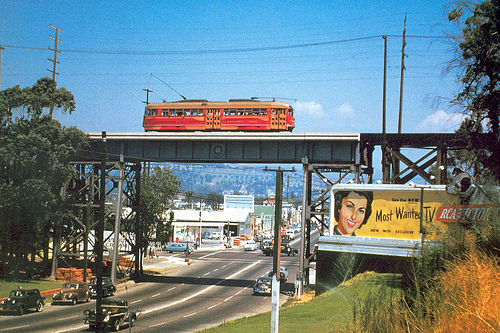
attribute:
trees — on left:
[0, 75, 96, 280]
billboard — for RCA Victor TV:
[313, 178, 496, 257]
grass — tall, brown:
[437, 258, 497, 326]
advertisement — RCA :
[435, 166, 499, 225]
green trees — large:
[13, 105, 105, 243]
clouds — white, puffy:
[294, 94, 471, 131]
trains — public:
[143, 79, 309, 156]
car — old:
[1, 288, 47, 315]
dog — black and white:
[442, 168, 484, 221]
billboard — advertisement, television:
[336, 189, 498, 244]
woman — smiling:
[326, 187, 386, 247]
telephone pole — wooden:
[273, 172, 280, 278]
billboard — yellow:
[289, 180, 496, 253]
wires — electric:
[4, 27, 499, 90]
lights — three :
[345, 173, 422, 188]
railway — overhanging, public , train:
[38, 122, 499, 266]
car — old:
[85, 294, 140, 331]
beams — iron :
[87, 130, 347, 295]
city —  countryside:
[87, 164, 364, 204]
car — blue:
[167, 237, 201, 267]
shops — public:
[155, 181, 310, 255]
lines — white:
[0, 249, 282, 331]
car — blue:
[173, 243, 189, 260]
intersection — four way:
[176, 242, 315, 279]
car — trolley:
[146, 87, 286, 126]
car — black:
[10, 285, 49, 315]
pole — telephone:
[29, 12, 74, 83]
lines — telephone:
[155, 38, 332, 79]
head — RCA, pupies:
[445, 164, 475, 199]